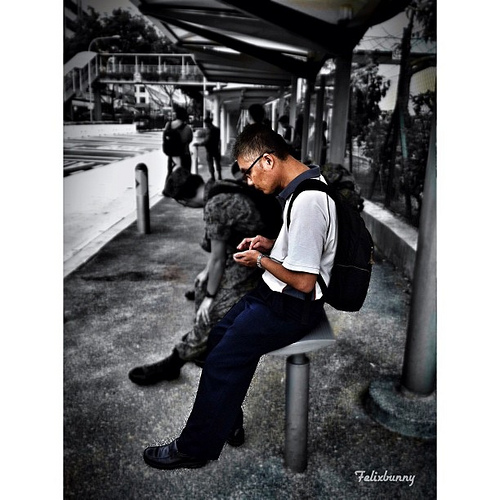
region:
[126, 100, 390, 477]
several people waiting at a train station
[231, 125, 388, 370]
a man sitting on a bench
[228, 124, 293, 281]
a man looking at his cellphone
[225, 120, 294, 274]
a man typing on his cellphone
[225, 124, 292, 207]
the head of a man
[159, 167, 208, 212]
the head of a man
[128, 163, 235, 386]
a soldier dressed in camouflage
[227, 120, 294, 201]
a man wearing glasses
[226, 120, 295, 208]
a man with black hair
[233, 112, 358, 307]
a man wearing a white and gray shirt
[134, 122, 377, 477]
this man is the only part of the photo in color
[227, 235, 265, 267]
the man is using a cell phone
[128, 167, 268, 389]
the man beside him is in fatigues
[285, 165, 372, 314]
the man wears a back pack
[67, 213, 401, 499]
the ground is covered in grass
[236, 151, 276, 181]
the man wears glasses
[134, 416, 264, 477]
the man wears black loafers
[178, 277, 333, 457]
the man wears blue pants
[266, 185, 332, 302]
the man is in a white t-shirt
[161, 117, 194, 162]
the person in the background carries a backpack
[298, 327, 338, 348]
man is sitting on a bench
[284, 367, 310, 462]
a metal pole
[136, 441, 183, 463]
black shoes the man is wearing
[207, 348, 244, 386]
the man is wearing pants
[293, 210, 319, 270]
a t shirt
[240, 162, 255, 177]
man is wearing glasses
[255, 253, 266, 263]
a watch on the wrist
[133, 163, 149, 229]
a pole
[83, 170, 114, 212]
the sidewalk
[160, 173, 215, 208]
a persons head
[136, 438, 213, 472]
the man's left foot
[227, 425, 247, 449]
the man's right foot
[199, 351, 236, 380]
the man's left knee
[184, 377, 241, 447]
the man's left leg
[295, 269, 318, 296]
the man's left elbow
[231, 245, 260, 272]
the man's left hand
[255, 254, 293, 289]
the man's left arm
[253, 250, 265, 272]
silver watch on the man's left arm.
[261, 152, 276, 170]
the man's left ear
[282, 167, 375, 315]
black backpack on the man's back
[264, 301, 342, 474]
silver bench with no back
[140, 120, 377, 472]
man carrying black backpack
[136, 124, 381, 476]
man looking down at his hands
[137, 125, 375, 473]
colored man in black and white photo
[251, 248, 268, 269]
silver watch on left wrist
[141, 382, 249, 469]
man in black dress shoes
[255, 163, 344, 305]
white shirt with blue collar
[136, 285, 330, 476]
man in dark blue jeans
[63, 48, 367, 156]
pedestrian walkway above street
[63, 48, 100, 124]
stairs leading to pedestrian walkway